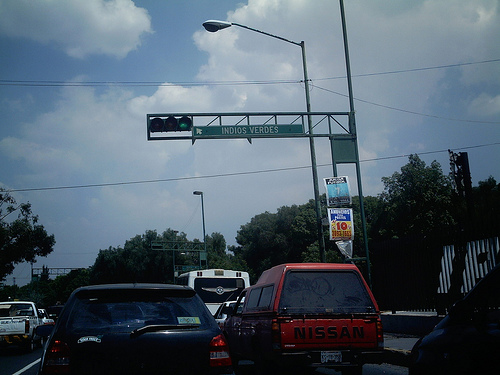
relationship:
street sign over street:
[195, 123, 309, 135] [3, 358, 20, 371]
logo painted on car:
[292, 323, 371, 342] [239, 260, 384, 365]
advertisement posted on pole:
[323, 176, 352, 209] [333, 163, 341, 176]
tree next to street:
[367, 171, 433, 288] [3, 358, 20, 371]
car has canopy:
[239, 260, 384, 365] [260, 267, 284, 282]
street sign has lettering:
[195, 123, 309, 135] [223, 128, 278, 134]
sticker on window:
[177, 315, 203, 326] [80, 297, 201, 326]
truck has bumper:
[0, 297, 44, 347] [1, 334, 28, 342]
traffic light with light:
[147, 116, 201, 136] [176, 114, 195, 134]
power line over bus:
[62, 164, 318, 191] [192, 269, 248, 296]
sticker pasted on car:
[177, 315, 203, 326] [41, 286, 228, 372]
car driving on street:
[239, 260, 384, 365] [3, 358, 20, 371]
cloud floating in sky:
[18, 9, 146, 54] [152, 18, 190, 71]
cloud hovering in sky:
[370, 12, 483, 70] [152, 18, 190, 71]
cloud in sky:
[18, 9, 146, 54] [152, 18, 190, 71]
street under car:
[3, 358, 20, 371] [239, 260, 384, 365]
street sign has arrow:
[195, 123, 309, 135] [195, 128, 201, 134]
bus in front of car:
[192, 269, 248, 296] [239, 260, 384, 365]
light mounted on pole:
[205, 17, 232, 35] [238, 20, 310, 47]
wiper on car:
[138, 324, 196, 331] [41, 286, 228, 372]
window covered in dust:
[284, 270, 371, 319] [293, 299, 302, 308]